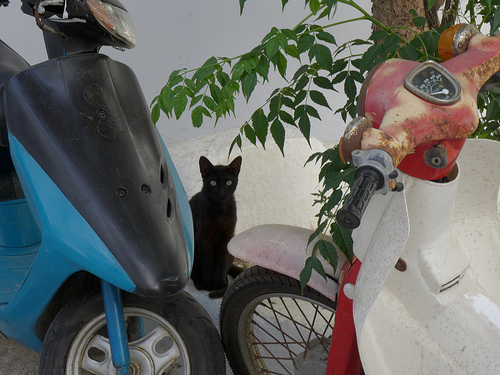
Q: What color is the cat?
A: Black.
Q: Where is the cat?
A: Behind the bikes.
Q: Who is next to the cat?
A: No one.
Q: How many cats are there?
A: One.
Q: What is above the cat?
A: A plant.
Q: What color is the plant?
A: Green.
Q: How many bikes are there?
A: Two.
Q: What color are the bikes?
A: Red and blue.